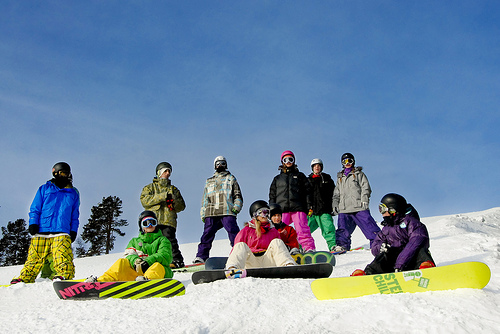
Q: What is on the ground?
A: Snow.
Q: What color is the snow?
A: White.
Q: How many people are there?
A: Nine.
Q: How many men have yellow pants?
A: One.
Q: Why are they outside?
A: They are snowboarding.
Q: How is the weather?
A: Sunny.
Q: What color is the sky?
A: Blue.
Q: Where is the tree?
A: Behind the people.